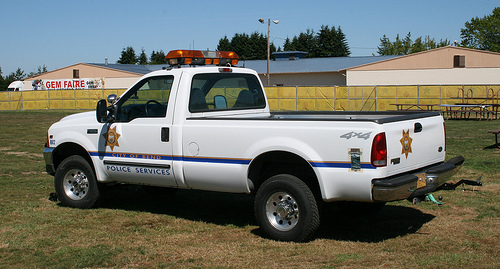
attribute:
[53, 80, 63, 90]
letter — written 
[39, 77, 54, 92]
letter — written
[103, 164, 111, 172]
letter — written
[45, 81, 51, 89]
letter — written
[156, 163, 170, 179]
letter — written 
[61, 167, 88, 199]
rim — silver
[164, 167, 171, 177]
letter — written 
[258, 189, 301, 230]
rim — silver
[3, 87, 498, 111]
fence — yellow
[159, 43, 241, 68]
lights — yellow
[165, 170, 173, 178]
letter — written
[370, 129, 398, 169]
light — red brake